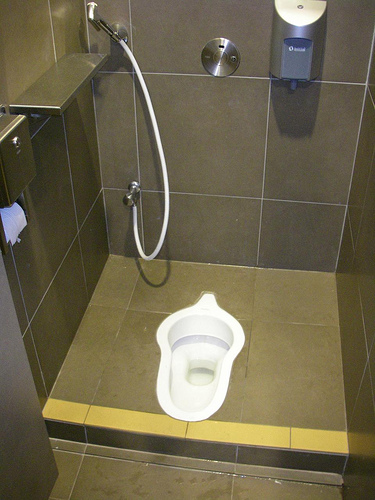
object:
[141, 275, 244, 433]
toilet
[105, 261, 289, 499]
ground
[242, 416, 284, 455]
yellow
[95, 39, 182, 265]
hose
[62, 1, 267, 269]
wall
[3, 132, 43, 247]
toilet paper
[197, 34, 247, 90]
flush button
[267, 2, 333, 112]
hand sanitizer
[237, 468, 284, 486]
grout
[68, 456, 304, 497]
floor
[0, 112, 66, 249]
dispenser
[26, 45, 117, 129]
shelf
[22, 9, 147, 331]
walls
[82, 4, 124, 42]
handle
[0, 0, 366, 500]
bathroom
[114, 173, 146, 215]
shower cord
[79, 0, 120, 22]
shower head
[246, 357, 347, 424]
tile